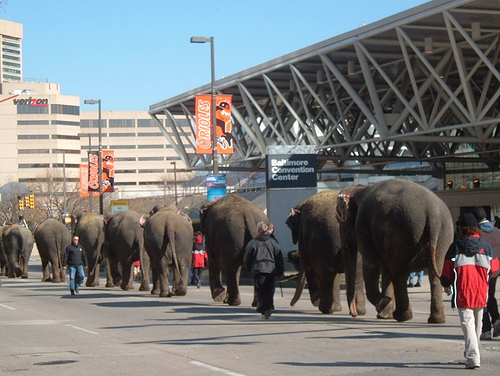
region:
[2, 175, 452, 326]
line of elephants on a road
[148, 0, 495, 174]
several metal beams making a roof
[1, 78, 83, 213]
tall off white office building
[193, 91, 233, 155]
sports team banner on light pole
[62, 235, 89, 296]
man in black coat walking down the street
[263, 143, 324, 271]
gray sign on side of the road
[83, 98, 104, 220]
tall metal street light pole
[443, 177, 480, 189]
two traffic lights by a building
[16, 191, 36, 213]
orange street lights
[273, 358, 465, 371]
shadow of a man on the road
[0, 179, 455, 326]
Group of elephants walking in a parade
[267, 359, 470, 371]
Shadow of the man on the ground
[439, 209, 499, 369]
Man walking near the elephant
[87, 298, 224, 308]
Shadow of the elephant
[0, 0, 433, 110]
Clear blue sky in the back ground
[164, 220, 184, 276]
Tail of the elephant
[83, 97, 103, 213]
Street lamp on the side of the road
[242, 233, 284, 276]
Black sweater worn by the man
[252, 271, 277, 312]
black pants worn by man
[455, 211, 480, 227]
black hat on the man's head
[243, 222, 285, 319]
man walking next to elephants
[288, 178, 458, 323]
two elephants walking in the road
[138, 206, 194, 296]
a single elephant walking in the road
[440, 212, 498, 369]
lady in a red jacket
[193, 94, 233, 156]
orange banner on a light pole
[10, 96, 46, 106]
verizon logo on building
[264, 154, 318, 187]
baltimore convention center sign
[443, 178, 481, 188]
two lights on the side of a building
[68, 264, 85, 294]
blue denim pants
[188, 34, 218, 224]
tall light pole for the street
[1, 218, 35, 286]
The elephant is gray.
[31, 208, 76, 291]
The elephant is gray.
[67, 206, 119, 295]
The elephant is gray.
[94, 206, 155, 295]
The elephant is gray.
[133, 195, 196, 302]
The elephant is gray.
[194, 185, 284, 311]
The elephant is gray.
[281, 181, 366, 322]
The elephant is gray.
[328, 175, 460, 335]
The elephant is gray.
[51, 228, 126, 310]
The man is walking.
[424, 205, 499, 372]
The man is walking.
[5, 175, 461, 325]
elephants walking down the street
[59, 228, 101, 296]
man wearing a black jacket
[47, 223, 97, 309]
man wearing jean pants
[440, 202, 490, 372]
man wearing beige pants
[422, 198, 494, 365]
man wearing red coat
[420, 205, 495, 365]
man wearing black hat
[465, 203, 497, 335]
man wearing brown jacket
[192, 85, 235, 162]
orange sign on pole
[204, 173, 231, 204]
blue sign on pole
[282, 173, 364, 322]
elephant with dirt on it's back